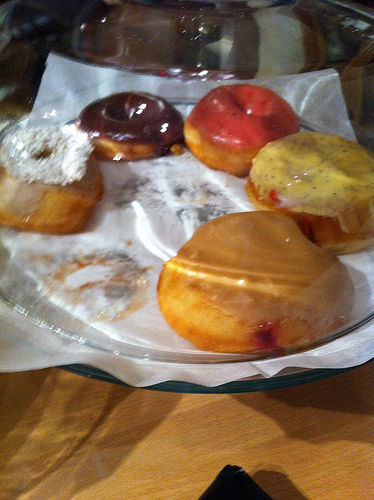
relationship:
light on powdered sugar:
[133, 99, 147, 118] [0, 122, 101, 190]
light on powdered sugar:
[157, 121, 172, 135] [0, 122, 101, 190]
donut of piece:
[156, 208, 354, 358] [0, 122, 104, 236]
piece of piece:
[240, 130, 371, 251] [0, 122, 104, 236]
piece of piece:
[181, 79, 301, 178] [0, 122, 104, 236]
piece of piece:
[77, 89, 184, 162] [77, 89, 184, 162]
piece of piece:
[0, 122, 104, 236] [0, 122, 104, 236]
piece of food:
[0, 122, 104, 236] [4, 121, 103, 234]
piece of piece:
[170, 140, 181, 159] [0, 122, 104, 236]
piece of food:
[62, 151, 87, 185] [4, 121, 103, 234]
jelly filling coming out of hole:
[250, 308, 296, 360] [238, 320, 295, 358]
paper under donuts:
[6, 41, 372, 389] [5, 57, 372, 374]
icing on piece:
[238, 112, 372, 228] [244, 130, 374, 251]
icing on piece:
[68, 73, 193, 181] [77, 89, 184, 162]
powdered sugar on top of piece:
[2, 110, 95, 182] [0, 122, 104, 236]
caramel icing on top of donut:
[179, 208, 334, 314] [160, 204, 362, 358]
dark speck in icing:
[310, 183, 323, 193] [248, 130, 374, 216]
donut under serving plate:
[156, 208, 354, 358] [0, 94, 374, 394]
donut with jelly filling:
[160, 204, 362, 358] [253, 318, 281, 349]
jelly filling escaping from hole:
[253, 318, 281, 349] [254, 312, 295, 356]